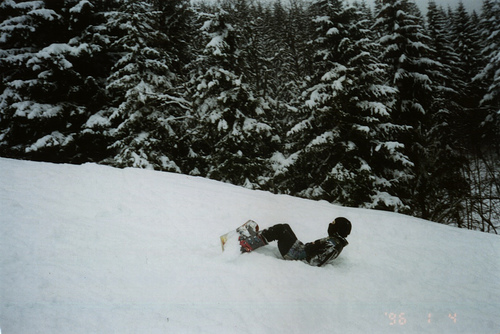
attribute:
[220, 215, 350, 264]
man — laying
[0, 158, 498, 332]
snow — white, covered slope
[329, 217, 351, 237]
hat — black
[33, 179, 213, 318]
snow — white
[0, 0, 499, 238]
trees — covered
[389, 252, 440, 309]
snow — white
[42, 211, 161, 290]
snow — white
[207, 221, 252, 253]
board — covered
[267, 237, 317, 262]
pants — black, snow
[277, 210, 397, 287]
person — eyes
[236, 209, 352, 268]
man — black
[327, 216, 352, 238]
ski mask — ski , black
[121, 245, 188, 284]
snow — white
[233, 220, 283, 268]
boots — dark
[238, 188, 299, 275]
pants — black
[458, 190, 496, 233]
branch — bare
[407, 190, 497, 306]
hill — side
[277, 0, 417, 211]
tree — large, green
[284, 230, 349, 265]
jacket — snow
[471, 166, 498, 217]
branches — brown, tree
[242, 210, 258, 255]
snow boots — grey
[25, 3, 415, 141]
evergreen trees — tall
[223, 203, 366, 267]
person — lying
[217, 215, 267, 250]
skis — pair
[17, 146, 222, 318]
slope — snow